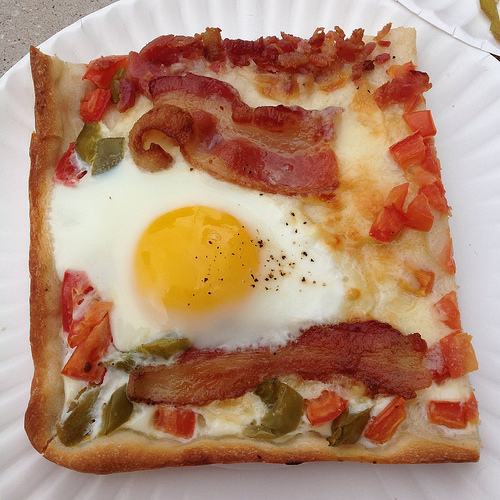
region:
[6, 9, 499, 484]
Pizza on a white dish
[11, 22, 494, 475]
Slice of pizza is square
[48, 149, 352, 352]
One egg over a pizza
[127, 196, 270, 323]
Egg yolk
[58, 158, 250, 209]
White of egg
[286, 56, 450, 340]
Cheese melted on pizza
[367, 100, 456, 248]
Cubes of pepper on top of pizza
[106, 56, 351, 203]
Slice of bacon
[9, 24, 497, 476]
Pizza is on a white dish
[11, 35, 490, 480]
Crust is golden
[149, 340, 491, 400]
bacon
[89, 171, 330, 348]
egg sunny side up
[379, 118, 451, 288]
diced red tomato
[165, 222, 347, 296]
pepper sprinkled on egg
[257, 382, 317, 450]
jalapeno on the egg white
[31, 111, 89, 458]
crispy bread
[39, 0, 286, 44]
white paper plate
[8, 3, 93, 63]
gray countertop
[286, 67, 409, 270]
melted cheese on bread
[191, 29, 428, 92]
crispy bacon crumbles on bread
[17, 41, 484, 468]
food on a plate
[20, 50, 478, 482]
square cut of breakfast style pizza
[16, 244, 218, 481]
golden crust on breakfast pizza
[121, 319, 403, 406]
cooked bacon on top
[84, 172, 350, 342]
soft boiled egg in center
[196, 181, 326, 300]
pepper on top of egg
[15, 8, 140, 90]
pizza on white paper plate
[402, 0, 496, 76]
several paper plates overlap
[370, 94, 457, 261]
diced pieces of red vegetable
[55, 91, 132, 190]
diced pieces of green vegetable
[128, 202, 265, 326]
the yellow yolk of an egg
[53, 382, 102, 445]
a green pepper on a pizza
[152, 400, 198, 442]
a red pepper on a pizza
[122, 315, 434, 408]
a strip of bacon on a pizza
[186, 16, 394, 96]
crumbled bacon on a pizza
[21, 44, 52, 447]
the crust of a pizza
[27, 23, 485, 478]
a slice of pizza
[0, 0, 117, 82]
a gray table under the plate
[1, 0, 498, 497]
a white paper plate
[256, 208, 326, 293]
black pepper on an egg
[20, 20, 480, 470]
breakfast pizza on paper plate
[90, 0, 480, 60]
fluted edges of white plate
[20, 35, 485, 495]
corner slice of breakfast meal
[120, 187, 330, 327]
pepper sprinkled on top of yolk and egg white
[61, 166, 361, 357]
egg cooked sunny side up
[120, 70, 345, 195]
slice of bacon with curled fat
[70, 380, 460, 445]
diced pepper along edge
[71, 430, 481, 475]
brown crust of breakfast pizza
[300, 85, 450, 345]
melted and browned cheese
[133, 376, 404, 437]
mix of red and green peppers